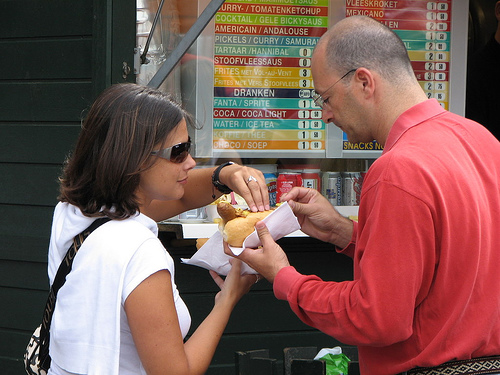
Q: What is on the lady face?
A: Shades.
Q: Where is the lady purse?
A: Shoulder.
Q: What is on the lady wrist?
A: A watch.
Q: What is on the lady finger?
A: A ring.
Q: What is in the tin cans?
A: Drink.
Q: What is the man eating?
A: A hotdog.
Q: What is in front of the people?
A: Food stand.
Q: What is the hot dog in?
A: Napkin.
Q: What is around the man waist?
A: A belt.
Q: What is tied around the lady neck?
A: A sweater.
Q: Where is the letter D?
A: On the sign.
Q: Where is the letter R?
A: On the sign.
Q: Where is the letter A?
A: On the sign.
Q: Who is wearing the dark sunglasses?
A: The dark haired woman.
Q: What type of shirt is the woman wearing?
A: A white shirt.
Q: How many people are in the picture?
A: Two.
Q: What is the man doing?
A: Holding food.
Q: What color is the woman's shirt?
A: White.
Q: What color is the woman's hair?
A: Brown.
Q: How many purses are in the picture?
A: One.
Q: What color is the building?
A: Black.